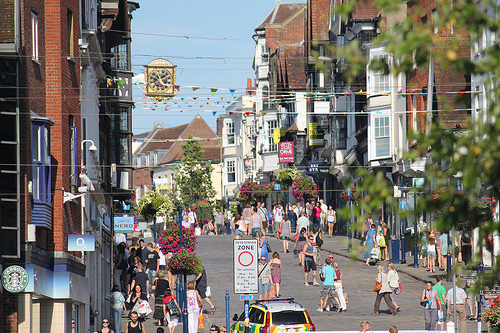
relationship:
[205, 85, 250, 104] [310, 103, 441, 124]
flags on line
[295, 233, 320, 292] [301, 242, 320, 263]
man in tanktop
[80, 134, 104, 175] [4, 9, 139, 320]
light on building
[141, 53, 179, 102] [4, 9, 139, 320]
clock on building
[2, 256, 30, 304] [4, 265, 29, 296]
sign reads starbucks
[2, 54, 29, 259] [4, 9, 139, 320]
ladder on building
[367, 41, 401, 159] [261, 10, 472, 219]
windows on building